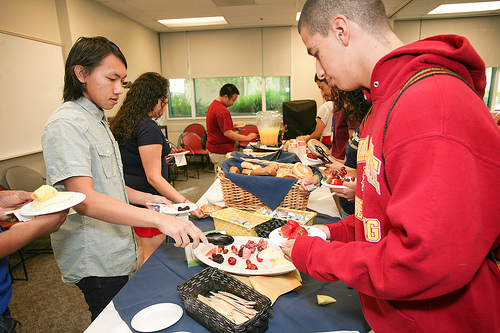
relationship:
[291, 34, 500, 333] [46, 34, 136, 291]
hoodie on boy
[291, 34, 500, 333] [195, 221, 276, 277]
hoodie helping with food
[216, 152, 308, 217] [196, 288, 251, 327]
basket with spoons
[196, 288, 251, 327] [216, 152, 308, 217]
spoons in basket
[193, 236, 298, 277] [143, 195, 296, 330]
plate on table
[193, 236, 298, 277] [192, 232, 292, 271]
plate on plate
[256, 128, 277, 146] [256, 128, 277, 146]
fruit juice has fruit juice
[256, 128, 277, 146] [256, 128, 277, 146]
fruit juice in fruit juice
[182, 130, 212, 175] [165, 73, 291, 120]
red chair by window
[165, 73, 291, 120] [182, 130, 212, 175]
window has red chair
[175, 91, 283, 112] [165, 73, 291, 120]
greens byb window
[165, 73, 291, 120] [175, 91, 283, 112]
window near greens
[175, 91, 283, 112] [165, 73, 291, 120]
greens near window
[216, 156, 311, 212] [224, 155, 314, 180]
basket has bread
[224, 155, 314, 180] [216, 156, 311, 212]
bread in basket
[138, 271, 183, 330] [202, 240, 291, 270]
table with food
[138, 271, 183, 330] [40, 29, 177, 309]
table near boy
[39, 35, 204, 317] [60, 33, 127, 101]
boy has long hair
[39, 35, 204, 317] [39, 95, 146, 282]
boy wearing green shirt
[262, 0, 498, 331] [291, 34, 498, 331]
boy wearing hoodie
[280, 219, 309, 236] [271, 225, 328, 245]
strawberries on plate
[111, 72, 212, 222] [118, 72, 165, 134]
person has hair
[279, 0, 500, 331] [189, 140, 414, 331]
boy reaching toward food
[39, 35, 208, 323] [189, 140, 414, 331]
boy reaching toward food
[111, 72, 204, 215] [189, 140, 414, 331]
person reaching toward food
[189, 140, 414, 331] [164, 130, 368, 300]
food on buffett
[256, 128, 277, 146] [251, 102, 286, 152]
fruit juice in container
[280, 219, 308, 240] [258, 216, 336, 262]
strawberries on plate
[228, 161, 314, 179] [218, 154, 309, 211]
bread in basket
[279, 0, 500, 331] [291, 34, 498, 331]
boy wearing hoodie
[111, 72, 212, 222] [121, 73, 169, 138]
person has hair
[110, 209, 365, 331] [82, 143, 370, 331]
tablecloth on table